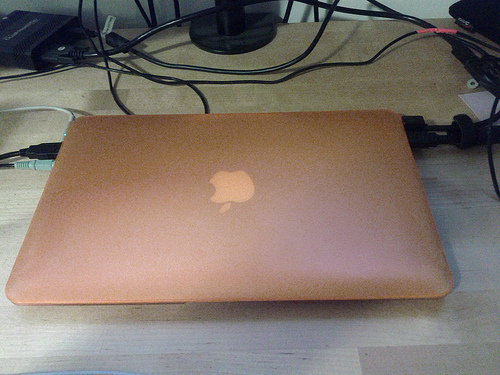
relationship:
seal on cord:
[416, 28, 458, 35] [188, 26, 416, 87]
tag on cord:
[99, 14, 117, 39] [108, 32, 216, 93]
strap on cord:
[446, 108, 478, 153] [476, 115, 497, 147]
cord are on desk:
[84, 0, 461, 61] [1, 13, 483, 115]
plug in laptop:
[9, 156, 56, 174] [6, 109, 456, 306]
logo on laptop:
[208, 169, 256, 215] [6, 109, 456, 306]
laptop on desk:
[6, 109, 456, 306] [0, 17, 500, 375]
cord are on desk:
[84, 0, 461, 61] [0, 17, 500, 375]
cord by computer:
[84, 0, 461, 61] [30, 88, 443, 321]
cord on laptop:
[438, 125, 499, 146] [6, 109, 456, 306]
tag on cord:
[99, 11, 119, 30] [52, 22, 302, 82]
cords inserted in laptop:
[9, 95, 84, 193] [9, 98, 461, 299]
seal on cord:
[416, 28, 458, 35] [93, 22, 458, 72]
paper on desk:
[458, 90, 500, 121] [0, 17, 500, 375]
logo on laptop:
[202, 153, 261, 217] [6, 109, 456, 306]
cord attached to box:
[84, 0, 461, 61] [0, 9, 85, 72]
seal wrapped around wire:
[415, 24, 457, 35] [79, 21, 499, 84]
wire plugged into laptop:
[2, 140, 62, 172] [6, 109, 456, 306]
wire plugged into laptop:
[0, 159, 55, 170] [6, 109, 456, 306]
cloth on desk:
[3, 20, 499, 372] [0, 17, 500, 375]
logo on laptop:
[208, 169, 256, 215] [5, 110, 499, 304]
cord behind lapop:
[84, 0, 461, 61] [6, 110, 455, 298]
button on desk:
[465, 77, 481, 90] [0, 17, 500, 375]